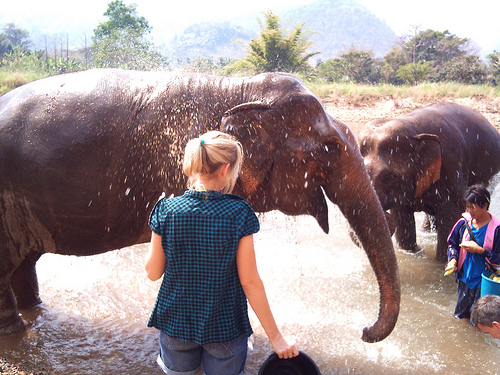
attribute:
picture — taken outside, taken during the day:
[4, 2, 499, 370]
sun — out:
[5, 2, 498, 50]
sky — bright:
[6, 0, 499, 35]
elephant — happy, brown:
[5, 60, 404, 351]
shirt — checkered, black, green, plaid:
[145, 187, 259, 345]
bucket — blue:
[476, 266, 499, 298]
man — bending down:
[468, 290, 499, 345]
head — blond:
[171, 122, 253, 212]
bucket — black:
[253, 350, 324, 374]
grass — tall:
[315, 79, 492, 108]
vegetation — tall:
[1, 1, 496, 81]